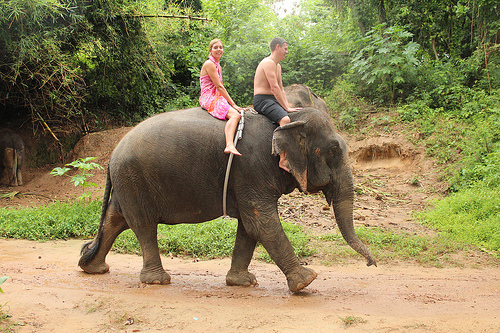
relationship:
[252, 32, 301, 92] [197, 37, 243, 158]
man and woman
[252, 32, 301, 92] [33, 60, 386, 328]
man riding an elephant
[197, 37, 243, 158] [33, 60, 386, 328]
woman riding an elephant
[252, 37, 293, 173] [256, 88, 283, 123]
man wearing shorts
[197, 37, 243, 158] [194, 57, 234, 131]
woman wearing dress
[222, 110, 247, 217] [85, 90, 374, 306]
harness around an elephant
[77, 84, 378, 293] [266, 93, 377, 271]
elephant has head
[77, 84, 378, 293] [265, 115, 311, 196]
elephant has ear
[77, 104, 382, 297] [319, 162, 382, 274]
elephant has trunk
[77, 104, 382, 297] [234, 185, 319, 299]
elephant has leg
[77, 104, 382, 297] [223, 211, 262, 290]
elephant has leg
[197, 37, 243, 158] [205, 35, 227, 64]
woman has head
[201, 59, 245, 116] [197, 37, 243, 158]
arm has woman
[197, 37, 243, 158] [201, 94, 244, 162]
woman has leg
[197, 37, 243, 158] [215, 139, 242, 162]
woman has foot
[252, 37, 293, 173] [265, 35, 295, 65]
man has head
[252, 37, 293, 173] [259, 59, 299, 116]
man has arm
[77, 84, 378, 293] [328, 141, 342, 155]
elephant has eye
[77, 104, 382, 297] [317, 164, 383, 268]
elephant has trunk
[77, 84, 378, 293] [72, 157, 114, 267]
elephant has tail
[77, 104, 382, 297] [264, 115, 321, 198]
elephant has ear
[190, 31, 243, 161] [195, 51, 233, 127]
woman in dress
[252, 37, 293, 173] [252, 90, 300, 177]
man in shorts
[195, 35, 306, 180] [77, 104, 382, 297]
couple riding on elephant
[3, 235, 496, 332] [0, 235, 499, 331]
ground covered in dirt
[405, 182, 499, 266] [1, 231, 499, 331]
grass growing beside path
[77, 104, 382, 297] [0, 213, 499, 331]
elephant walking on path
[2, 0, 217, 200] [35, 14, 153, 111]
trees have leaves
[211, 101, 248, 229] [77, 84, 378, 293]
harness around elephant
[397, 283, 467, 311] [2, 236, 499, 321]
elephant tracks in mud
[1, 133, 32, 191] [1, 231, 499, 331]
stump beside path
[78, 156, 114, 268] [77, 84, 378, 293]
tail on a elephant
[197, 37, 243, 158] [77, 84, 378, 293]
woman on a elephant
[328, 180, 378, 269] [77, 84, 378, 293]
trunk on a elephant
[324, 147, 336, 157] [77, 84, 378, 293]
eye on a elephant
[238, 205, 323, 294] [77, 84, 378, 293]
leg on a elephant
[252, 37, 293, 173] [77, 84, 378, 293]
man on a elephant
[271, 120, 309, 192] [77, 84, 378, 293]
ear on a elephant